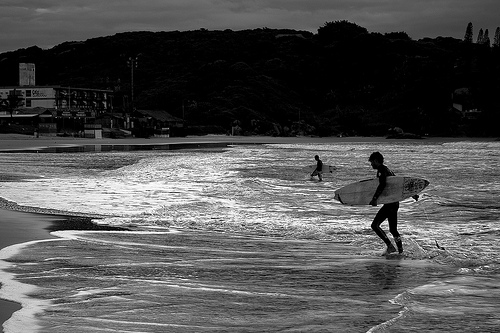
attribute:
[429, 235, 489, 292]
ripples — small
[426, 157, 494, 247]
ripples — small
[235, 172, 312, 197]
ripples — small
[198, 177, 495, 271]
ripples — small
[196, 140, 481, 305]
people — wet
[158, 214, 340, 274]
ripples — small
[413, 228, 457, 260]
ripples — small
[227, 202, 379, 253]
waves — small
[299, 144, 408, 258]
people — surfing